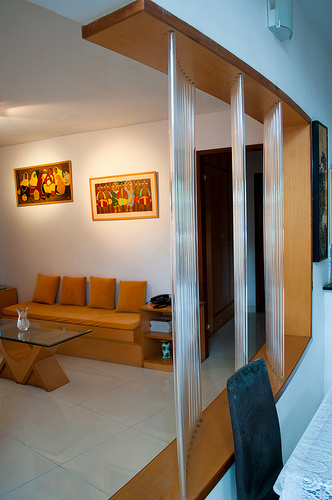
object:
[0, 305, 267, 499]
matting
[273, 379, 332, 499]
tablecloth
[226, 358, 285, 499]
chair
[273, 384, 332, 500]
table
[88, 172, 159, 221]
picture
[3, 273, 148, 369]
couch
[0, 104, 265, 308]
wall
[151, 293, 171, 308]
phone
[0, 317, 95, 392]
coffee table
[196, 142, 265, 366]
frame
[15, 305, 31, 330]
vase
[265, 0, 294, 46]
fire alarm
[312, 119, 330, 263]
picture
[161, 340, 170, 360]
candle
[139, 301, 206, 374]
side table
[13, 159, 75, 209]
picture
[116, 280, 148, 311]
pillow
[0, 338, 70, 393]
base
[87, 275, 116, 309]
pillow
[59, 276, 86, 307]
pillow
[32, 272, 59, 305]
pillow